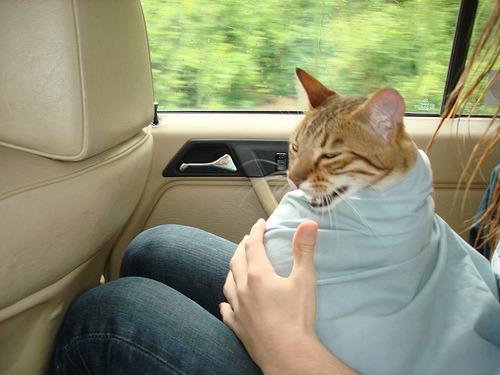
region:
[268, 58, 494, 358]
A cat wrapped in blue blanket.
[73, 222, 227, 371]
Knees of girl holding cat.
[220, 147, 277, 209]
A car door handle.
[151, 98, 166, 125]
A car door lock.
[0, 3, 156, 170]
Headrest on front seat of car.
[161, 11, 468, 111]
Side window of car.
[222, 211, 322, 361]
Hand of girl holding cat.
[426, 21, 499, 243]
Blonde hair of girl holding cat.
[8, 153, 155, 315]
Back of car's front seat.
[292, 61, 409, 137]
A cat's two ears.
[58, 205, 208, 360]
two bent knees clothed in jeans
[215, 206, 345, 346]
hand with curled fingers and an upright thumb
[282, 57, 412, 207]
cat with unhappy expression by window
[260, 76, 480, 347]
cat swaddled in blue fabric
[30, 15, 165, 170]
tan headrest for passenger in front seat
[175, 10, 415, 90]
passing greenery outside the moving car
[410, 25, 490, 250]
strands of long, light brown hair of seated passenger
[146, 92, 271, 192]
button, knob and handle on the inside of the car door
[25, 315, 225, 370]
outside seam on leg of dungarees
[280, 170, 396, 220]
open mouth and whiskers of cat making sound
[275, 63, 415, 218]
a brown meowing cat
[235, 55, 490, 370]
a cat wrapped in a blue blanket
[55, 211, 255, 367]
blue jeans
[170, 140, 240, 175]
a chrome car door handle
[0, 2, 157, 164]
a brown car headrest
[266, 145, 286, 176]
power window controls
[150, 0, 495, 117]
a rear car window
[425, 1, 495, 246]
long brown hair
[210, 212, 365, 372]
a human hand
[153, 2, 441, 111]
greenery passing by car window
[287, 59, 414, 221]
The cat is striped white and brown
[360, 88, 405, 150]
The ear is pink on the inside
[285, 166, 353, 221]
The cat has his mouth open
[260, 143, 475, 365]
The cat is wrapped in a blue blanket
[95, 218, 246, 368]
This person is wearing jeans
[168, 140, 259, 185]
The vehicle has a silver door handle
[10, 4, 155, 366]
The vehicles interior is cream colored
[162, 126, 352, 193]
This part of the door is black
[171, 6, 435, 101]
There are green trees outdoors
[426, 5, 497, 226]
This persons hair is brown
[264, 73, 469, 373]
cat wrapped in a sheet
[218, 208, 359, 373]
woman's hand holding cat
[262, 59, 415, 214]
cat's head visible above sheet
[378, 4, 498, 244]
person's long hair is near cat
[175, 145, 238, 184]
silver door handle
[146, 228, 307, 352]
cat is being held on someone's lap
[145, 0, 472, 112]
blurred foliage visible through window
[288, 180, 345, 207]
cat's mouth is open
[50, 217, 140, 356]
person's knees are close to seat in front of person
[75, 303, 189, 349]
person is wearing blue jeans